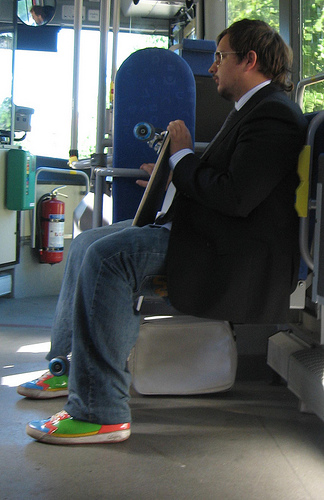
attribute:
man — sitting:
[193, 29, 270, 117]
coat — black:
[190, 99, 277, 282]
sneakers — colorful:
[18, 371, 135, 455]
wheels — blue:
[122, 111, 158, 149]